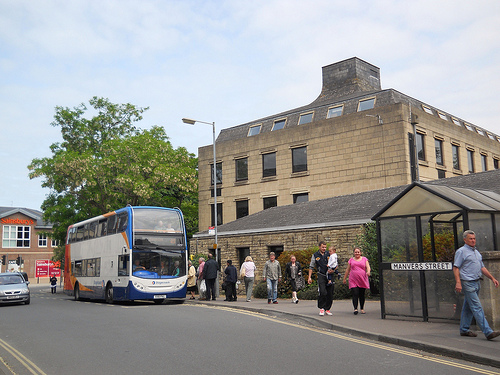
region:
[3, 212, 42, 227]
orange words on front of building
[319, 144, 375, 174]
tan bricks on the wall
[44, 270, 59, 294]
person standing on street corner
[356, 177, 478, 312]
glass enclosure on sidewalk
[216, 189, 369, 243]
gray roof on building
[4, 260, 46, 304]
silver car on street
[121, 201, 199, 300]
long glass front on the bus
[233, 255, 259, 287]
tan purse over woman's shoulder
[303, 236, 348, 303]
man carrying baby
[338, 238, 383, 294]
woman wearing short sleeve pink dress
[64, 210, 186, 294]
A two level bus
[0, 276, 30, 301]
A silver car passing the bus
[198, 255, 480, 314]
A group of people entering and exiting the bus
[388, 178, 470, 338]
The Manvers Street bus stop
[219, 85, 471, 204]
A tall brick building next to the bus stop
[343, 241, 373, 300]
A woman wearing a pink shirt and black pants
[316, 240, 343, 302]
A man carrying a child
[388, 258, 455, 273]
A bus top sign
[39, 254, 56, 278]
A red directional sign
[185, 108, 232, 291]
A street lamp next to a parked bus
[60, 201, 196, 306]
A two level passenger bus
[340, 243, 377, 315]
A woman in a pink shirt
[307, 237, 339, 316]
A man carrying a small child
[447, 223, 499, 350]
A man in a light blue shirt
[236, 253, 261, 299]
A woman in a light colored shirt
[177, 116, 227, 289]
A tall metal light pole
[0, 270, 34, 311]
A small silver car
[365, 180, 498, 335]
A bus stop canopy with a sign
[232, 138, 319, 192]
Windows on the side of a building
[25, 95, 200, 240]
A large deciduous tree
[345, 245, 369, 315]
A woman wearing a pink top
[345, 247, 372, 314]
A woman wearing black pants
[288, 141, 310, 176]
A rectangular window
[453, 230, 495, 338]
A man wearing a blue shirt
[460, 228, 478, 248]
A man with gray hair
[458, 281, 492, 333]
A man's blue jeans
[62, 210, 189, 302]
A double decker bus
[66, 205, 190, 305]
A passenger bus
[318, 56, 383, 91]
A brown brick chimney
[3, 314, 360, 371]
A paved road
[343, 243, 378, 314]
lady wearing a pink dress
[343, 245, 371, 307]
lady wearing black leggings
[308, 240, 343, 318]
guy holding a child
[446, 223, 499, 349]
guy walking on sidewalk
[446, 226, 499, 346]
guy wearing a blue shirt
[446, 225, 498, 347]
guy wearing blue denim jeans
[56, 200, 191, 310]
double decker bus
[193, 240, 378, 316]
people walking on the sidewalk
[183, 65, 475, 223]
brick building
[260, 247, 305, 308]
lady and man walking together